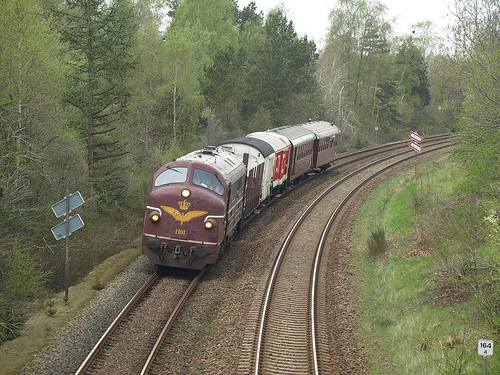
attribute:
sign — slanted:
[50, 191, 82, 216]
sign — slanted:
[50, 215, 82, 239]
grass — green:
[386, 167, 499, 367]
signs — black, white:
[404, 127, 426, 154]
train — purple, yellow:
[134, 157, 234, 275]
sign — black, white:
[470, 335, 497, 364]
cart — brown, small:
[115, 149, 261, 259]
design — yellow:
[161, 200, 208, 237]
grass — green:
[1, 238, 141, 373]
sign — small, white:
[472, 334, 498, 359]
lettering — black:
[477, 340, 493, 349]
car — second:
[226, 128, 296, 201]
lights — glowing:
[148, 181, 216, 231]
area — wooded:
[8, 1, 492, 318]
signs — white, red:
[411, 127, 421, 156]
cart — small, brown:
[301, 117, 340, 172]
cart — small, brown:
[266, 122, 316, 184]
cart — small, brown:
[244, 129, 291, 188]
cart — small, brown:
[216, 148, 263, 219]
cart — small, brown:
[141, 144, 246, 271]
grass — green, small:
[408, 243, 460, 296]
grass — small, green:
[359, 156, 499, 373]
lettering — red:
[269, 152, 289, 181]